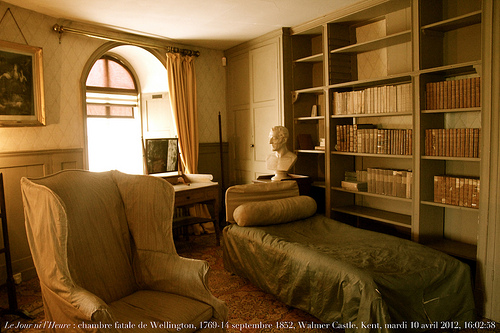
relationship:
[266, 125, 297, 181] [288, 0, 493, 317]
bust in front of bookshelf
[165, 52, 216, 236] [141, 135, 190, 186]
curtain behind mirror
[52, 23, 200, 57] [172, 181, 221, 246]
curtain rod above desk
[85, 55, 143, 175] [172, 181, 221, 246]
window behind desk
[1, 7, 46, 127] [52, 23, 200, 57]
framed picture next to curtain rod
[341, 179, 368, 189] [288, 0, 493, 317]
book on bookshelf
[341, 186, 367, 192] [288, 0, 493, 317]
book on bookshelf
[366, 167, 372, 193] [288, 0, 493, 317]
book on bookshelf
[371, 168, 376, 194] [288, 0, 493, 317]
book on bookshelf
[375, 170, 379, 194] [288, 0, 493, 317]
book on bookshelf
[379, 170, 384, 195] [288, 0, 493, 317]
book on bookshelf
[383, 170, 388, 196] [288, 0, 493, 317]
book on bookshelf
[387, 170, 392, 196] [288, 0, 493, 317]
book on bookshelf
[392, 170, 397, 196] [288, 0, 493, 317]
book on bookshelf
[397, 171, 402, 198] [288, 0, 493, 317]
book on bookshelf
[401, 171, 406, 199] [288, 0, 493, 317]
book on bookshelf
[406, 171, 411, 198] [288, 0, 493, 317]
book on bookshelf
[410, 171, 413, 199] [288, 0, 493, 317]
book on bookshelf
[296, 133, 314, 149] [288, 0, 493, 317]
book on bookshelf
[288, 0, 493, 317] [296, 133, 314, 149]
bookshelf has a book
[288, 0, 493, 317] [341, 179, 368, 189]
bookshelf has a book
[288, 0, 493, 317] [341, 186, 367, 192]
bookshelf has a book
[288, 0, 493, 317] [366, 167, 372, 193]
bookshelf has a book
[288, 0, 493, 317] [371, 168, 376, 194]
bookshelf has a book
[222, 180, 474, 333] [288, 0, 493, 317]
sofa chair by bookshelf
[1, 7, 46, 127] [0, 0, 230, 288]
framed picture on wall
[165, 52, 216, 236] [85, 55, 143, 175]
curtain on window